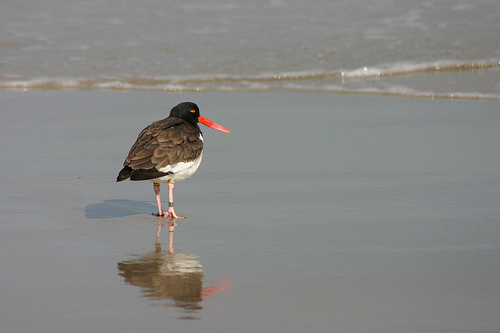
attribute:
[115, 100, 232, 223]
bird — standing, brown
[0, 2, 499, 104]
water — shallow, body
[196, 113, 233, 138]
beak — long, orange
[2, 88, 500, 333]
beach — wet, brown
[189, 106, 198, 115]
eye — red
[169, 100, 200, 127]
head — black